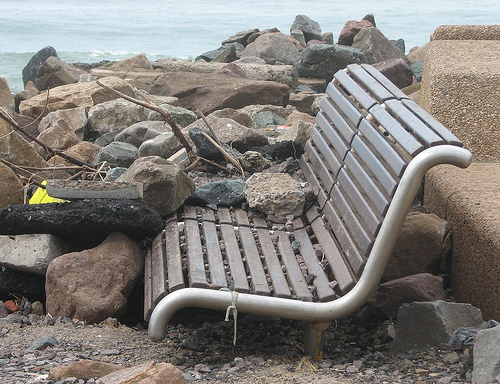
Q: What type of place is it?
A: It is a shore.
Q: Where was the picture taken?
A: It was taken at the shore.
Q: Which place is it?
A: It is a shore.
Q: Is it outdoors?
A: Yes, it is outdoors.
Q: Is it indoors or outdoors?
A: It is outdoors.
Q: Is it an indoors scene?
A: No, it is outdoors.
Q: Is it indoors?
A: No, it is outdoors.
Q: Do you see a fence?
A: No, there are no fences.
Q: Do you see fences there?
A: No, there are no fences.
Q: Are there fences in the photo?
A: No, there are no fences.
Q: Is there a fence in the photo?
A: No, there are no fences.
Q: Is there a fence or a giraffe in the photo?
A: No, there are no fences or giraffes.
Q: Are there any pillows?
A: No, there are no pillows.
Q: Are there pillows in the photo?
A: No, there are no pillows.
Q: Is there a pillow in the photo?
A: No, there are no pillows.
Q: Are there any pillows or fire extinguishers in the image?
A: No, there are no pillows or fire extinguishers.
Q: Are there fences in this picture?
A: No, there are no fences.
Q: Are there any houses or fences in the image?
A: No, there are no fences or houses.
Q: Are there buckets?
A: No, there are no buckets.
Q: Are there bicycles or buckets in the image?
A: No, there are no buckets or bicycles.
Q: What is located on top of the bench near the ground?
A: The rocks are on top of the bench.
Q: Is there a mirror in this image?
A: No, there are no mirrors.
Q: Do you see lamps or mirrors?
A: No, there are no mirrors or lamps.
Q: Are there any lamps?
A: No, there are no lamps.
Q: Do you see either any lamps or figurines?
A: No, there are no lamps or figurines.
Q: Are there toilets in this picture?
A: No, there are no toilets.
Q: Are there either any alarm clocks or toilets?
A: No, there are no toilets or alarm clocks.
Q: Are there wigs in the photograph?
A: No, there are no wigs.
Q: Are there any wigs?
A: No, there are no wigs.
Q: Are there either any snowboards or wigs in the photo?
A: No, there are no wigs or snowboards.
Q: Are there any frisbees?
A: No, there are no frisbees.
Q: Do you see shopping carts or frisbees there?
A: No, there are no frisbees or shopping carts.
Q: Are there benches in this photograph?
A: Yes, there is a bench.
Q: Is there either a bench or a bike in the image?
A: Yes, there is a bench.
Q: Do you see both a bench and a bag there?
A: No, there is a bench but no bags.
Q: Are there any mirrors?
A: No, there are no mirrors.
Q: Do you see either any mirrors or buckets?
A: No, there are no mirrors or buckets.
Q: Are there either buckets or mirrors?
A: No, there are no mirrors or buckets.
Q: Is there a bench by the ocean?
A: Yes, there is a bench by the ocean.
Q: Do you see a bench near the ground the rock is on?
A: Yes, there is a bench near the ground.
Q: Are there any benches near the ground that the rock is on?
A: Yes, there is a bench near the ground.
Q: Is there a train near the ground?
A: No, there is a bench near the ground.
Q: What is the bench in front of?
A: The bench is in front of the rocks.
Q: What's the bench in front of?
A: The bench is in front of the rocks.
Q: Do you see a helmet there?
A: No, there are no helmets.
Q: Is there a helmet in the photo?
A: No, there are no helmets.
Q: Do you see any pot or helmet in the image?
A: No, there are no helmets or pots.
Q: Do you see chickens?
A: No, there are no chickens.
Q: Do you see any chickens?
A: No, there are no chickens.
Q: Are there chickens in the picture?
A: No, there are no chickens.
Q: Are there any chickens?
A: No, there are no chickens.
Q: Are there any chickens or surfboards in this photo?
A: No, there are no chickens or surfboards.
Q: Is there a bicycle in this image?
A: No, there are no bicycles.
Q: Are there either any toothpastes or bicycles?
A: No, there are no bicycles or toothpastes.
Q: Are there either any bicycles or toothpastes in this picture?
A: No, there are no bicycles or toothpastes.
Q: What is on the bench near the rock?
A: The seat is on the bench.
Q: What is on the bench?
A: The seat is on the bench.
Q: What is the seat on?
A: The seat is on the bench.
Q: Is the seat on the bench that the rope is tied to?
A: Yes, the seat is on the bench.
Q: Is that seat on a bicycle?
A: No, the seat is on the bench.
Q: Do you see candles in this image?
A: No, there are no candles.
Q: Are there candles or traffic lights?
A: No, there are no candles or traffic lights.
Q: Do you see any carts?
A: No, there are no carts.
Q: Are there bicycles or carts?
A: No, there are no carts or bicycles.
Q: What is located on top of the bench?
A: The rocks are on top of the bench.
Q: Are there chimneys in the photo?
A: No, there are no chimneys.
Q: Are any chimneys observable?
A: No, there are no chimneys.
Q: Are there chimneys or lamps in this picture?
A: No, there are no chimneys or lamps.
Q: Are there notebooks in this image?
A: No, there are no notebooks.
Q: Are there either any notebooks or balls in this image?
A: No, there are no notebooks or balls.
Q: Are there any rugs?
A: No, there are no rugs.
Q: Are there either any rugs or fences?
A: No, there are no rugs or fences.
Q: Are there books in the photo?
A: No, there are no books.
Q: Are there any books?
A: No, there are no books.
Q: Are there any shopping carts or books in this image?
A: No, there are no books or shopping carts.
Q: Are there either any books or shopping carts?
A: No, there are no books or shopping carts.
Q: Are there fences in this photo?
A: No, there are no fences.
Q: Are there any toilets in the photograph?
A: No, there are no toilets.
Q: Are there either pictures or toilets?
A: No, there are no toilets or pictures.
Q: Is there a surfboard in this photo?
A: No, there are no surfboards.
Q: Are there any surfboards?
A: No, there are no surfboards.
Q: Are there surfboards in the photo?
A: No, there are no surfboards.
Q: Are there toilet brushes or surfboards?
A: No, there are no surfboards or toilet brushes.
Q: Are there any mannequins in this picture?
A: No, there are no mannequins.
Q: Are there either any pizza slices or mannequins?
A: No, there are no mannequins or pizza slices.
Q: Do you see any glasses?
A: No, there are no glasses.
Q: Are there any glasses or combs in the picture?
A: No, there are no glasses or combs.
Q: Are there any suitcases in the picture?
A: No, there are no suitcases.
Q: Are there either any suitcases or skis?
A: No, there are no suitcases or skis.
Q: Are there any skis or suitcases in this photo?
A: No, there are no suitcases or skis.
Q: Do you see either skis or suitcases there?
A: No, there are no suitcases or skis.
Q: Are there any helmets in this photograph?
A: No, there are no helmets.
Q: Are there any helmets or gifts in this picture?
A: No, there are no helmets or gifts.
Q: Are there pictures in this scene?
A: No, there are no pictures.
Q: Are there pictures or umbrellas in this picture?
A: No, there are no pictures or umbrellas.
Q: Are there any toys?
A: No, there are no toys.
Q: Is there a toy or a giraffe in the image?
A: No, there are no toys or giraffes.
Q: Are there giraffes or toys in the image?
A: No, there are no toys or giraffes.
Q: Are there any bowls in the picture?
A: No, there are no bowls.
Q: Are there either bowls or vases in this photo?
A: No, there are no bowls or vases.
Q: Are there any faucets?
A: No, there are no faucets.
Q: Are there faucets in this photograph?
A: No, there are no faucets.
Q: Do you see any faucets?
A: No, there are no faucets.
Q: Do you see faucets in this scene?
A: No, there are no faucets.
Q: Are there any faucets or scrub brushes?
A: No, there are no faucets or scrub brushes.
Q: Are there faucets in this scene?
A: No, there are no faucets.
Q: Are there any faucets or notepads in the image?
A: No, there are no faucets or notepads.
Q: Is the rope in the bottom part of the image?
A: Yes, the rope is in the bottom of the image.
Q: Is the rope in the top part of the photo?
A: No, the rope is in the bottom of the image.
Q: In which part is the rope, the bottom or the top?
A: The rope is in the bottom of the image.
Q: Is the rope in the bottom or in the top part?
A: The rope is in the bottom of the image.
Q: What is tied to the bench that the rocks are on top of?
A: The rope is tied to the bench.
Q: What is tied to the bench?
A: The rope is tied to the bench.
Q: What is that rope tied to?
A: The rope is tied to the bench.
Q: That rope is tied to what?
A: The rope is tied to the bench.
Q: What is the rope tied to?
A: The rope is tied to the bench.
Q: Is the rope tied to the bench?
A: Yes, the rope is tied to the bench.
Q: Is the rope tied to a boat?
A: No, the rope is tied to the bench.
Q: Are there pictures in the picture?
A: No, there are no pictures.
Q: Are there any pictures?
A: No, there are no pictures.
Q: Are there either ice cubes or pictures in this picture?
A: No, there are no pictures or ice cubes.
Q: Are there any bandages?
A: No, there are no bandages.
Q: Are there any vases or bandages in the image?
A: No, there are no bandages or vases.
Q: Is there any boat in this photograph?
A: No, there are no boats.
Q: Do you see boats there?
A: No, there are no boats.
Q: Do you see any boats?
A: No, there are no boats.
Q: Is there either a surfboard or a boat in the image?
A: No, there are no boats or surfboards.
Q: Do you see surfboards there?
A: No, there are no surfboards.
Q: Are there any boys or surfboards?
A: No, there are no surfboards or boys.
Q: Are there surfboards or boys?
A: No, there are no surfboards or boys.